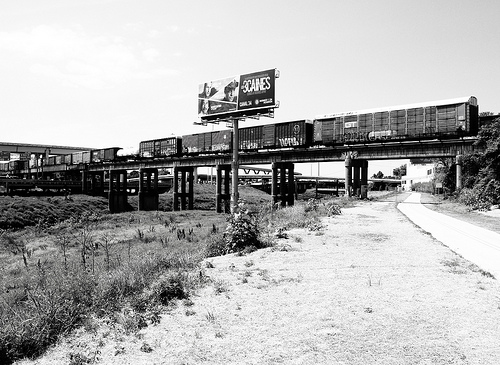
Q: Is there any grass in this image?
A: Yes, there is grass.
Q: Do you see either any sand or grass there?
A: Yes, there is grass.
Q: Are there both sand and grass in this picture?
A: Yes, there are both grass and sand.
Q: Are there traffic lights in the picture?
A: No, there are no traffic lights.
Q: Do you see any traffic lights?
A: No, there are no traffic lights.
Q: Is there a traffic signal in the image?
A: No, there are no traffic lights.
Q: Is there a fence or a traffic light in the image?
A: No, there are no traffic lights or fences.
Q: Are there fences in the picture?
A: No, there are no fences.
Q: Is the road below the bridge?
A: Yes, the road is below the bridge.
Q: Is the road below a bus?
A: No, the road is below the bridge.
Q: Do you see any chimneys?
A: No, there are no chimneys.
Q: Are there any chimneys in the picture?
A: No, there are no chimneys.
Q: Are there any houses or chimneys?
A: No, there are no chimneys or houses.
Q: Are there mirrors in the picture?
A: No, there are no mirrors.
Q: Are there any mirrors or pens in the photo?
A: No, there are no mirrors or pens.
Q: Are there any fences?
A: No, there are no fences.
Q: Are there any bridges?
A: Yes, there is a bridge.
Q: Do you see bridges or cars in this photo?
A: Yes, there is a bridge.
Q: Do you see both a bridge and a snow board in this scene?
A: No, there is a bridge but no snowboards.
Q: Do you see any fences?
A: No, there are no fences.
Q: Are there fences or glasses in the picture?
A: No, there are no fences or glasses.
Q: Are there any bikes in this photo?
A: No, there are no bikes.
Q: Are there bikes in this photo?
A: No, there are no bikes.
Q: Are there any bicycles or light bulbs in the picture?
A: No, there are no bicycles or light bulbs.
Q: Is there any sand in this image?
A: Yes, there is sand.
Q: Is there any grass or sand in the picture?
A: Yes, there is sand.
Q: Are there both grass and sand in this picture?
A: Yes, there are both sand and grass.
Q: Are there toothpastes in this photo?
A: No, there are no toothpastes.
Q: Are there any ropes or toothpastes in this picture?
A: No, there are no toothpastes or ropes.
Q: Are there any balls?
A: No, there are no balls.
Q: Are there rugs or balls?
A: No, there are no balls or rugs.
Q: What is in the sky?
A: The clouds are in the sky.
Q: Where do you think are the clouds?
A: The clouds are in the sky.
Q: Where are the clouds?
A: The clouds are in the sky.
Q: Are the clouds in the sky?
A: Yes, the clouds are in the sky.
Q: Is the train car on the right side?
A: Yes, the train car is on the right of the image.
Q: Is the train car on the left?
A: No, the train car is on the right of the image.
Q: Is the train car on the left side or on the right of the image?
A: The train car is on the right of the image.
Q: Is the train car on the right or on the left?
A: The train car is on the right of the image.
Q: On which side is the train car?
A: The train car is on the right of the image.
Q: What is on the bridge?
A: The train car is on the bridge.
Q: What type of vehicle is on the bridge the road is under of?
A: The vehicle is a train car.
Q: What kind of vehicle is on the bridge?
A: The vehicle is a train car.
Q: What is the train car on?
A: The train car is on the bridge.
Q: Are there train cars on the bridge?
A: Yes, there is a train car on the bridge.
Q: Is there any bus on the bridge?
A: No, there is a train car on the bridge.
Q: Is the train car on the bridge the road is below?
A: Yes, the train car is on the bridge.